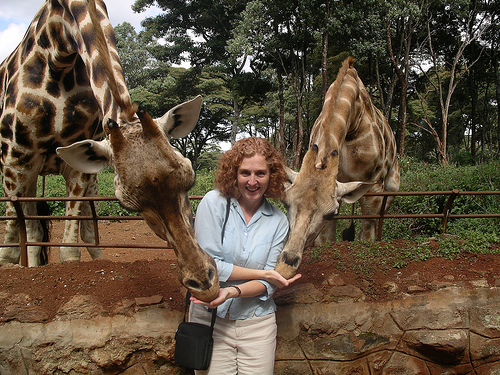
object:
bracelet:
[228, 285, 241, 299]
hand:
[190, 287, 229, 308]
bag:
[174, 290, 216, 371]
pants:
[193, 295, 279, 375]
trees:
[105, 7, 191, 115]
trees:
[189, 2, 283, 144]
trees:
[303, 7, 332, 97]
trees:
[411, 2, 489, 166]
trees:
[378, 2, 420, 160]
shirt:
[193, 188, 289, 322]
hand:
[265, 269, 301, 289]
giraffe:
[0, 0, 218, 302]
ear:
[282, 164, 299, 189]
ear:
[56, 139, 113, 174]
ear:
[154, 94, 202, 138]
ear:
[337, 181, 377, 203]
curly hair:
[216, 137, 288, 200]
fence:
[1, 188, 498, 265]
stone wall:
[0, 282, 498, 373]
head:
[105, 120, 219, 303]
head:
[274, 171, 340, 279]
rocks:
[335, 299, 490, 352]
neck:
[70, 2, 141, 126]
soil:
[0, 235, 497, 323]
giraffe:
[274, 58, 400, 279]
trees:
[463, 34, 497, 167]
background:
[104, 8, 426, 84]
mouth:
[274, 263, 297, 280]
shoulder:
[197, 188, 234, 213]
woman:
[192, 136, 303, 375]